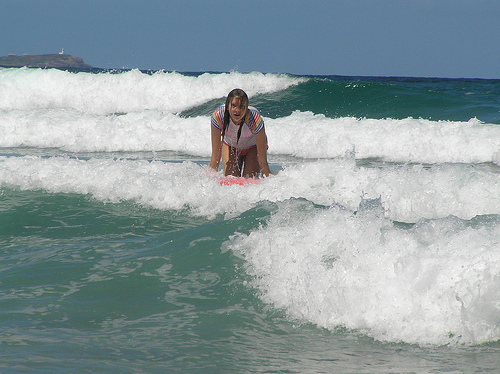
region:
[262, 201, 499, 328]
this is a snow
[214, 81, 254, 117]
this is a person`s head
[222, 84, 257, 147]
this is a person`s hair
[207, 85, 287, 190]
this is a person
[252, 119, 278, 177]
this is a person`s hand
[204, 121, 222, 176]
this is a person`s hand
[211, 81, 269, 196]
woman on pink board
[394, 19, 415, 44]
white clouds in blue sky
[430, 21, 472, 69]
white clouds in blue sky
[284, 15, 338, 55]
white clouds in blue sky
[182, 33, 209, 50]
white clouds in blue sky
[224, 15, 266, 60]
white clouds in blue sky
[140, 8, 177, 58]
white clouds in blue sky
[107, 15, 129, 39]
white clouds in blue sky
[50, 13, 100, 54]
white clouds in blue sky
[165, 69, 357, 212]
a woman on a surfboard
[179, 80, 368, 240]
a woman in the water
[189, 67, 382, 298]
a woman kneeling on surfboard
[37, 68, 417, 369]
a body of water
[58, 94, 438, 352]
a body of blue water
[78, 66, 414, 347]
a body of wavy water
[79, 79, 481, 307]
a body of water that is blue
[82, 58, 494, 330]
a body of water that is wavy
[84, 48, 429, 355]
a girl athat is wet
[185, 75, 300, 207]
a girl wearing a shirt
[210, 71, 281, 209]
female surfer on pink board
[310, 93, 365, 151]
white and green ocean waves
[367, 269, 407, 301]
white and green ocean waves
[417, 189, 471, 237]
white and green ocean waves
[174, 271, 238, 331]
white and green ocean waves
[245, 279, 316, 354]
white and green ocean waves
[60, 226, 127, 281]
white and green ocean waves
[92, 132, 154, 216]
white and green ocean waves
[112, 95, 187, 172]
white and green ocean waves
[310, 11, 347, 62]
white clouds in blue sky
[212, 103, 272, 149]
woman in white shirt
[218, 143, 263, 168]
woman in red trunks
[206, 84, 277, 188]
woman bent over in water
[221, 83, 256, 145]
woman with long blond wet hair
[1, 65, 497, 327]
white rushing waves in water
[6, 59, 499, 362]
blue green sea water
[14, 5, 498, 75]
clear blue cloudless sky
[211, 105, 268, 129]
shoulders of shirt with rainbow stripe design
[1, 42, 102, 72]
land mass in water in distance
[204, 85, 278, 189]
young woman swimming in ocean in the waves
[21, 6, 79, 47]
white clouds in blue sky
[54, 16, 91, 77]
white clouds in blue sky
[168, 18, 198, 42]
white clouds in blue sky